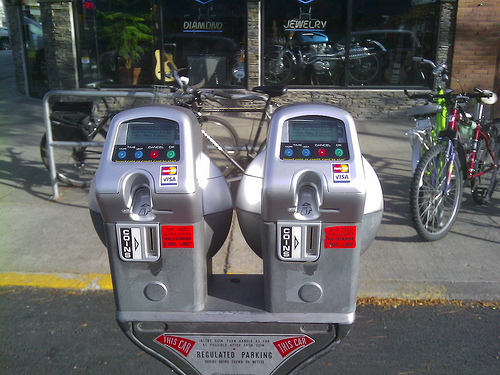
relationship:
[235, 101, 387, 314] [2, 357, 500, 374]
metal parking meter beside curb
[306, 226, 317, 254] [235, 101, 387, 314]
coin slot under metal parking meter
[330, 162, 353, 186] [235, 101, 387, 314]
credit card logo on metal parking meter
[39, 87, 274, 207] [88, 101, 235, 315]
bike rack behind parking meter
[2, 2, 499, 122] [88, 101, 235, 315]
store behind parking meter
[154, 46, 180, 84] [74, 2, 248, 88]
guitar in store window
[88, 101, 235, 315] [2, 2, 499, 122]
parking meter in front of store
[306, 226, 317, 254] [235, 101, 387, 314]
coin slot on metal parking meter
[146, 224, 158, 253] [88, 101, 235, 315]
coin slot on parking meter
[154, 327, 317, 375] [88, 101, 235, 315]
sign on parking meter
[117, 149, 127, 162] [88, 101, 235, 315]
button on parking meter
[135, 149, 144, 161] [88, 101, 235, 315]
button on parking meter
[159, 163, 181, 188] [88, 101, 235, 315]
credit card logo on parking meter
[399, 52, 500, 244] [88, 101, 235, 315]
bicycles are parked near parking meter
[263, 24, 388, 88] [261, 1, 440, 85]
motorcycle in front of store window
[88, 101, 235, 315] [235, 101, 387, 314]
parking meter next to or metal parking meter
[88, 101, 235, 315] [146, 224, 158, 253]
parking meter has a coin slot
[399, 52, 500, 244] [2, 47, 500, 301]
bicycles are on sidewalk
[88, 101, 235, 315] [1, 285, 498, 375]
parking meter on street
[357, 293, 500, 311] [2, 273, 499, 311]
leaves are on curb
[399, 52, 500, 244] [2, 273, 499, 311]
bicycles are parked on curb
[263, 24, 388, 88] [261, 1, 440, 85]
motorcycle in store window